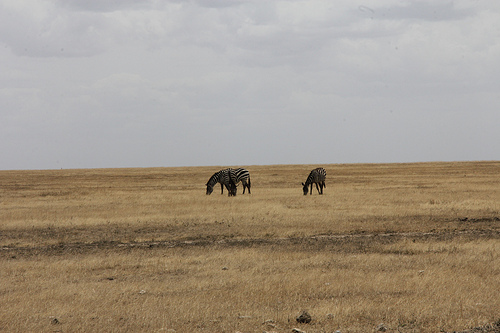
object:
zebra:
[301, 167, 326, 195]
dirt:
[0, 215, 500, 261]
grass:
[1, 160, 500, 333]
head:
[302, 182, 309, 196]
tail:
[320, 171, 326, 188]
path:
[0, 213, 500, 269]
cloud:
[0, 0, 500, 171]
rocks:
[49, 316, 59, 326]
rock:
[296, 310, 311, 323]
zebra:
[205, 168, 250, 197]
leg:
[242, 182, 250, 194]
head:
[205, 184, 214, 195]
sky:
[0, 0, 500, 171]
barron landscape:
[0, 0, 500, 329]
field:
[0, 161, 500, 327]